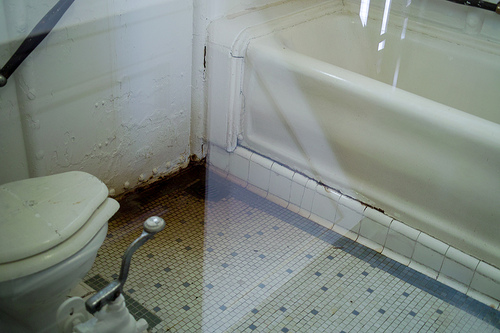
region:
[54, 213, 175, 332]
A foot pedal for flushing the toilet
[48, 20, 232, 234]
An area of wall needing repair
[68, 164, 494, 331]
Bathroom tile with small green spacing as design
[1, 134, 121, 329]
Toilet seat that has been damaged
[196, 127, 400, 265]
Baseboard of bathtub needing repair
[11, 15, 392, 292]
Corner of bathroom that needs to be replaced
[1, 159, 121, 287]
Cracked and discolored toilet seat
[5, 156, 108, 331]
white toilet bowl with lid down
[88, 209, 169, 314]
lever next to toilet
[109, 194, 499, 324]
patterned tiled floor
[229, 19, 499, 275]
white bathtub in the bathroom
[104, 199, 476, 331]
blue squares in the tile pattern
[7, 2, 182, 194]
white wall next to toilet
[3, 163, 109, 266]
lid on the toilet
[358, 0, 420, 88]
sunlight in the bathtub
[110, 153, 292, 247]
rust damage on the floor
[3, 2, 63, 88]
black bar next to the wall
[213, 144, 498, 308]
white tiles below tub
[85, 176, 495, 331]
small square floor tiles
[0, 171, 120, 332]
side of white toilet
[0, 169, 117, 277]
cover on toilet seat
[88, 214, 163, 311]
pedal on edge of metal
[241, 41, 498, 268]
side of white tub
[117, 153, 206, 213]
rust stain on bottom of wall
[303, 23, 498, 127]
inside of white tub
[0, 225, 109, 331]
side of toilet bowl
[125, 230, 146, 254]
light reflection on metal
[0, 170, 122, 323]
off-white toilet in bathroom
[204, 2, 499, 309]
white tub in bathroom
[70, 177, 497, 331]
tiles on bathroom floor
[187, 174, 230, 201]
drain in floor of bathroom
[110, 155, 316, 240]
rust stains on bathroom floor and wall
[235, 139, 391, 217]
crack forming between tub and tile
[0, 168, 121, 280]
worn out toilet seat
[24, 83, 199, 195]
damaged paint on wall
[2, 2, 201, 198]
white wall of bathroom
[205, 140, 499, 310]
tile lining bottom edge of tub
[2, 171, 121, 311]
this is a toilet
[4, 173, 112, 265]
this is a toilet cover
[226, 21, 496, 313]
this is a bath tub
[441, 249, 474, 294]
this is a tile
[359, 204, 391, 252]
this is a tile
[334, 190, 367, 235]
this is a tile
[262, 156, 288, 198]
this is a tile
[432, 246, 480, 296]
this is a tile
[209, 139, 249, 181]
this is a tile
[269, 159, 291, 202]
this is a tile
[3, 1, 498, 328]
reflection on window glass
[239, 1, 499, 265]
tub in corner of room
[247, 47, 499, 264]
side of white tub